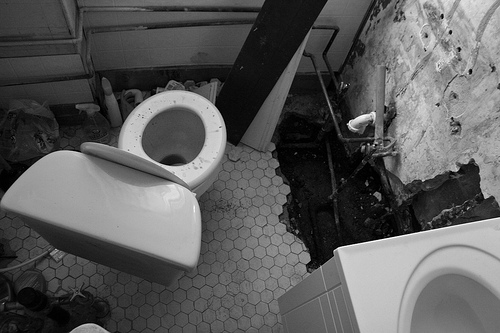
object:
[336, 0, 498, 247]
wall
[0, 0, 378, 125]
wall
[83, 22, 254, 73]
license plate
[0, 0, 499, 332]
bathroom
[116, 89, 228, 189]
seat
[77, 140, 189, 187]
lid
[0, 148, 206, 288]
tank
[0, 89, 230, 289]
toilet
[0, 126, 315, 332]
floor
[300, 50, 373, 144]
plumbing pipes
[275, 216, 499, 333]
sink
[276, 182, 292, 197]
torn tile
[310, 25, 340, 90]
plaster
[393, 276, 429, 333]
edge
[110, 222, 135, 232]
part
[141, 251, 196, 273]
edge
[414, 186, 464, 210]
part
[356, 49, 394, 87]
edge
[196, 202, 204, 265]
edge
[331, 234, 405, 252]
edge